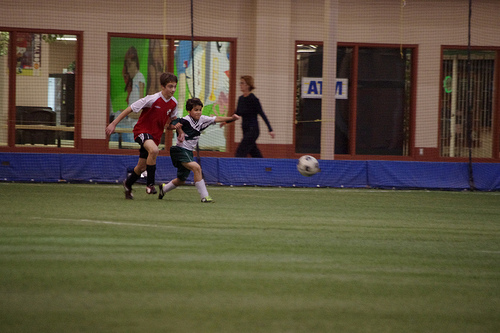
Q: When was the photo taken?
A: Daytime.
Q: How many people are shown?
A: Three.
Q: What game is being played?
A: Soccer.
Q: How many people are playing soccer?
A: Two.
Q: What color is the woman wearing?
A: Black.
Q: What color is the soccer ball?
A: Black and white.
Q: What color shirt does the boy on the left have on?
A: Red.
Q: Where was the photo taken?
A: In a park.